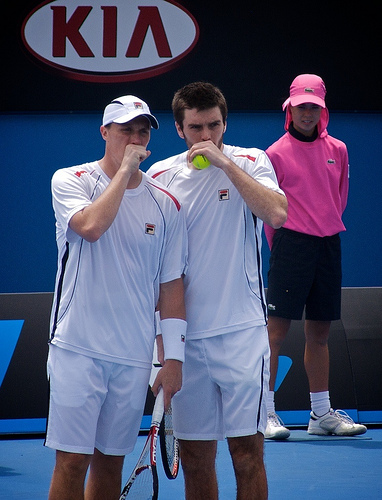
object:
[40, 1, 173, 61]
kia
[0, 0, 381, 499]
background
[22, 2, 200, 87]
logo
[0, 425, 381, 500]
ground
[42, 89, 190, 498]
man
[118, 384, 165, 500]
tennis racket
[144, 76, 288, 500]
man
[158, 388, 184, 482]
tennis racket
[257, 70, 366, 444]
person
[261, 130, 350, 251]
shirt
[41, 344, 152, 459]
shorts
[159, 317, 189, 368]
wristband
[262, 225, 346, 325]
shorts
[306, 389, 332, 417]
socks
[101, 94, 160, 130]
hat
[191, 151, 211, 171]
ball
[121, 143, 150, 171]
hand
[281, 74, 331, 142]
hat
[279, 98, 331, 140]
flaps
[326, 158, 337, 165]
logo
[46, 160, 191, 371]
shirt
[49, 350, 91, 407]
pocket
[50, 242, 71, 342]
stripe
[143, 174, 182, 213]
stripes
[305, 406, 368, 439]
shoes